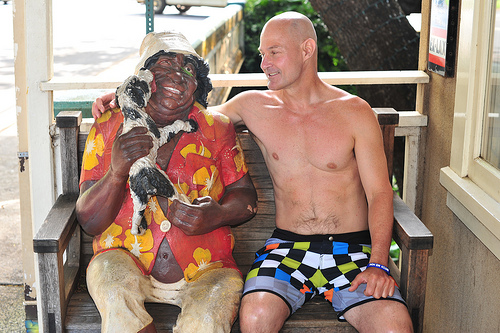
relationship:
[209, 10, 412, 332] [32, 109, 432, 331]
man sitting on bench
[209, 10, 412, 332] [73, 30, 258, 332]
man next to statue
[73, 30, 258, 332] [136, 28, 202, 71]
statue wearing hat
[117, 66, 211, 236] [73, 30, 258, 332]
dog licking statue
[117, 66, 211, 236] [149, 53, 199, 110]
dog licking face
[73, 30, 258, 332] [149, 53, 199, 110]
statue has face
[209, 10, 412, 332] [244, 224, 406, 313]
man wearing swim trunks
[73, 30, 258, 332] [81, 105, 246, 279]
statue wearing hawaiian shirt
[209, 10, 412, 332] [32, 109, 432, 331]
man on top of bench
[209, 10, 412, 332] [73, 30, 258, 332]
man hugging statue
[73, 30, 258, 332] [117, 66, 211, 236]
statue holding dog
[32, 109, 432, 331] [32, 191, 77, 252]
bench has armrest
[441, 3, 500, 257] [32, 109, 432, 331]
window in front of bench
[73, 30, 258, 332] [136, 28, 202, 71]
statue has hat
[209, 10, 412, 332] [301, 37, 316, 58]
man has left ear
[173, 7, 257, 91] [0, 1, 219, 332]
fence on side of street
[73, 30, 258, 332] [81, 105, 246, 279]
statue has hawaiian shirt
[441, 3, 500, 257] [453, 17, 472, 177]
window has frame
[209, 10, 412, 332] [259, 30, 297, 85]
man has face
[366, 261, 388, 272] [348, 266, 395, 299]
band on hand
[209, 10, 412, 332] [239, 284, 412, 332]
man has legs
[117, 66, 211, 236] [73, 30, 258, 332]
dog kissing statue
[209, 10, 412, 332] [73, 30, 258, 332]
man posing with statue